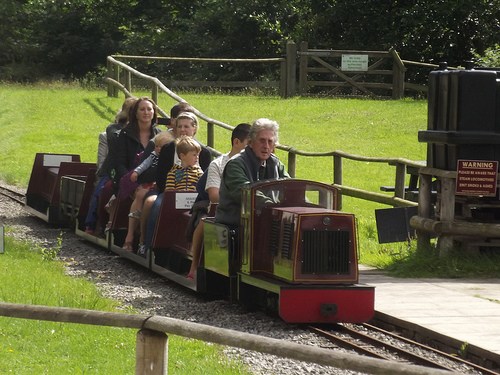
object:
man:
[213, 116, 293, 225]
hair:
[249, 117, 279, 146]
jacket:
[213, 145, 292, 225]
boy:
[163, 136, 205, 192]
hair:
[175, 136, 202, 159]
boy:
[127, 131, 175, 219]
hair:
[154, 131, 177, 148]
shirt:
[133, 149, 161, 176]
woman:
[145, 109, 214, 256]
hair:
[175, 111, 199, 137]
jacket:
[155, 136, 212, 194]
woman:
[117, 96, 165, 177]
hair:
[129, 97, 158, 132]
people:
[83, 97, 140, 235]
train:
[22, 152, 375, 326]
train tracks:
[303, 322, 499, 372]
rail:
[0, 303, 458, 373]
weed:
[382, 232, 471, 280]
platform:
[357, 270, 500, 357]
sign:
[374, 206, 423, 244]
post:
[403, 204, 418, 240]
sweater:
[164, 163, 204, 193]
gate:
[296, 44, 402, 102]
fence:
[105, 40, 499, 261]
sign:
[339, 53, 368, 71]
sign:
[454, 159, 499, 198]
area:
[1, 85, 432, 274]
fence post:
[332, 153, 343, 209]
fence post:
[286, 150, 296, 178]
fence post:
[206, 121, 216, 148]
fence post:
[150, 81, 159, 107]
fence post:
[125, 70, 133, 99]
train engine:
[240, 177, 377, 323]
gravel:
[0, 182, 500, 374]